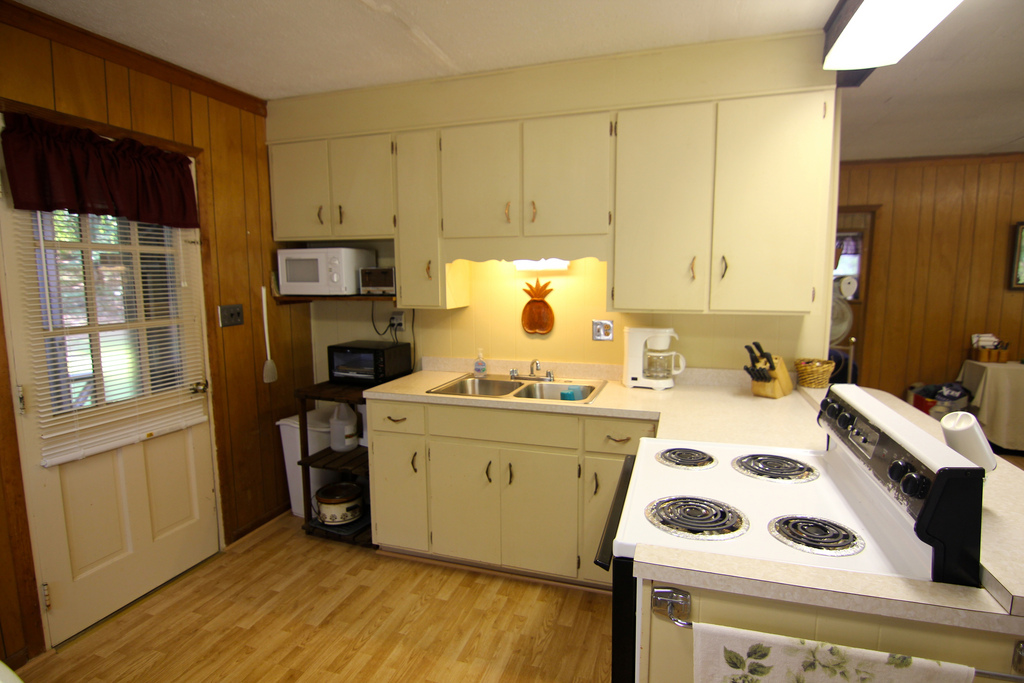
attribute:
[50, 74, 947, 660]
kitchen — white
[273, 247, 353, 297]
microwave — white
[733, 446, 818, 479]
burner — black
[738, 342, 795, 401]
block — knife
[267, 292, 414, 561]
shelf — small 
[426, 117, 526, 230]
cabinet door — white, wooden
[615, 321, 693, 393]
coffee pot — white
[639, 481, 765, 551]
stove — round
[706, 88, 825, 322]
cabinet door — white, wooden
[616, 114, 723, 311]
cabinet door — wooden, white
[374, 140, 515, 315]
cabinet door — white, wooden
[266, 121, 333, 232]
cabinet door — wooden, white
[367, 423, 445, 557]
cabinet door — white, wooden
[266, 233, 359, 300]
microwave — white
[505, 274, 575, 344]
pineapple — fake